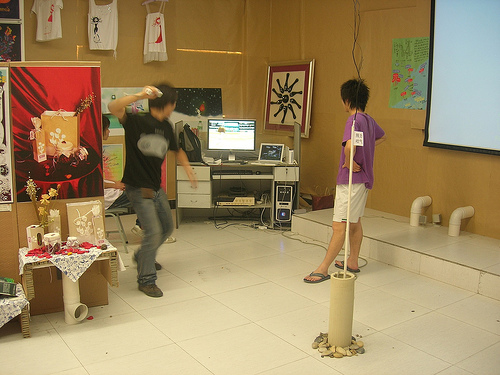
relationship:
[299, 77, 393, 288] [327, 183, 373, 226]
man wears shorts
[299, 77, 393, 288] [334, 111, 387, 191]
man wears shirt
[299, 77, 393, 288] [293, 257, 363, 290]
man wears sandals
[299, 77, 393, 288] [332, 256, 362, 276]
man wears sandal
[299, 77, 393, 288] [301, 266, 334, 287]
man wears sandal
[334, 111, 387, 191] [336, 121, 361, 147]
shirt has short sleeve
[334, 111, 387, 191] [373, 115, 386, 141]
shirt has short sleeve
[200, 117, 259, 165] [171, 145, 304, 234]
monitor on desk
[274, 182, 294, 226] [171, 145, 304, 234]
tower pc beneath desk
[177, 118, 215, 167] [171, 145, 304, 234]
backpack on desk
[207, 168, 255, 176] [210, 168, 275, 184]
keyboard on desk pull-out shelf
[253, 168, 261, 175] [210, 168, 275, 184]
mouse on desk pull-out shelf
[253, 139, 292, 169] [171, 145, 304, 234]
old terminal [?] on desk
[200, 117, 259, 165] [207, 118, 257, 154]
monitor has screen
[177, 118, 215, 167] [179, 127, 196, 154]
backpack has grey trim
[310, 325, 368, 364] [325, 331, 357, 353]
rocks in circle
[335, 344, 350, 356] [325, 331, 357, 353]
rock in circle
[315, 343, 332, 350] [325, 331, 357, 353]
rock in circle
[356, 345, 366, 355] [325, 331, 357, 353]
rock in circle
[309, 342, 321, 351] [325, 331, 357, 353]
rock in circle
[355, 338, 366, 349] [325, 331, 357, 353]
rock in circle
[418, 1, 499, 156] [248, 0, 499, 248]
screen on wall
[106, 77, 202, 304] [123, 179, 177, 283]
man wears jeans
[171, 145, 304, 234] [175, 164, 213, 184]
desk has drawer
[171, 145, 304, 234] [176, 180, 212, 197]
desk has drawer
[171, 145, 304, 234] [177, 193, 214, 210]
desk has drawer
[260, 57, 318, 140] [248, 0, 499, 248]
picture on wall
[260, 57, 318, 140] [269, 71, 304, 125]
picture has array of rays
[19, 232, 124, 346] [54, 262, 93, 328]
table has base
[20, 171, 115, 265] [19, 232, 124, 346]
lively items on table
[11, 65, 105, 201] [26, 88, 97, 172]
picture of still life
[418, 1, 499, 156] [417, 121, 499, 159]
screen has wrinkle at bottom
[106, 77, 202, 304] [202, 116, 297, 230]
man plays game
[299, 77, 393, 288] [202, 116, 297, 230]
man watches game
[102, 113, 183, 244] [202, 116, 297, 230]
man watches game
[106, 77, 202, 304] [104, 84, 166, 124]
man has arm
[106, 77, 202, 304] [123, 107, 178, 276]
man has body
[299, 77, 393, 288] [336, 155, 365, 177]
man has hand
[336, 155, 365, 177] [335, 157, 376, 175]
hand on waist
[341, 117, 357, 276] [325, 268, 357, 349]
pole in tube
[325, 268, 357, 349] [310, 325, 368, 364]
tube encircled by rocks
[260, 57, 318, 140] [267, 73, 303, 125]
picture of swirl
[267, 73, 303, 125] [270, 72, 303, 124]
swirl has rays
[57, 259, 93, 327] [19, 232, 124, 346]
pipe supports table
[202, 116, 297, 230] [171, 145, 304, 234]
game on desk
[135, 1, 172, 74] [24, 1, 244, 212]
garment hanging against wall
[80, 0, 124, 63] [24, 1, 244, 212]
garment hanging against wall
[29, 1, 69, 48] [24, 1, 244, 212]
garment hanging against wall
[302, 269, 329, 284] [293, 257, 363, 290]
foot in sandals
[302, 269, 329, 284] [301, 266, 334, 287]
foot in sandal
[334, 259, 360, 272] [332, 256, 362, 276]
foot in sandal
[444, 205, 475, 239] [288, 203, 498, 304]
pipes on platform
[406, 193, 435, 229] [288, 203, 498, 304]
pipe on platform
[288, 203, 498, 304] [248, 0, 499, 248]
platform connected to wall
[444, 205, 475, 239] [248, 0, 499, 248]
pipes seems to go through wall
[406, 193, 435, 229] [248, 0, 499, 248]
pipe seems to go through wall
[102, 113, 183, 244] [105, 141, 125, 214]
man wears shirt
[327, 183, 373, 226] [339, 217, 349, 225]
shorts have tag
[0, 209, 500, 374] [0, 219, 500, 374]
floor has tiles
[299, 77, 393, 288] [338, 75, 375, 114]
man has hair